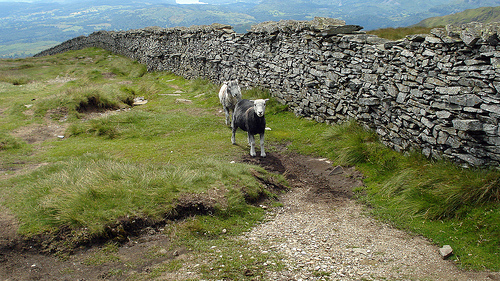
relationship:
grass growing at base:
[312, 119, 497, 224] [160, 93, 475, 159]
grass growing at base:
[0, 60, 498, 236] [160, 93, 475, 159]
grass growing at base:
[189, 74, 216, 96] [160, 93, 475, 159]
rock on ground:
[409, 239, 474, 280] [176, 167, 403, 252]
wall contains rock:
[293, 27, 499, 147] [452, 120, 481, 132]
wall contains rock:
[293, 27, 499, 147] [447, 92, 482, 106]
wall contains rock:
[293, 27, 499, 147] [434, 83, 463, 94]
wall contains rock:
[293, 27, 499, 147] [397, 91, 407, 102]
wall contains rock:
[293, 27, 499, 147] [423, 48, 434, 58]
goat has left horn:
[231, 98, 271, 157] [261, 96, 271, 102]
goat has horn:
[222, 97, 273, 154] [240, 95, 254, 121]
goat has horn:
[218, 79, 242, 125] [222, 77, 227, 91]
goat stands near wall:
[231, 98, 271, 157] [31, 13, 498, 170]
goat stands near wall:
[218, 79, 242, 125] [31, 13, 498, 170]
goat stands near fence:
[231, 98, 271, 157] [32, 17, 499, 168]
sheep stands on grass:
[217, 76, 267, 158] [4, 50, 101, 252]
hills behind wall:
[3, 2, 491, 23] [293, 27, 499, 147]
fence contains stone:
[127, 29, 217, 67] [196, 54, 206, 60]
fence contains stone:
[127, 29, 217, 67] [174, 52, 181, 57]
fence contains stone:
[127, 29, 217, 67] [184, 33, 194, 39]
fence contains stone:
[127, 29, 217, 67] [213, 54, 222, 57]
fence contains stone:
[127, 29, 217, 67] [205, 44, 212, 48]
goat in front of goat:
[231, 98, 271, 157] [218, 79, 242, 125]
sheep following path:
[219, 79, 271, 158] [225, 138, 498, 278]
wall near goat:
[353, 71, 412, 147] [215, 74, 245, 125]